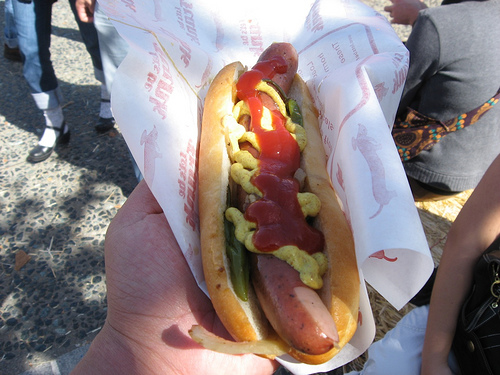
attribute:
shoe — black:
[17, 125, 68, 167]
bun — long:
[198, 62, 360, 367]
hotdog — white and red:
[194, 39, 365, 362]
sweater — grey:
[395, 7, 499, 182]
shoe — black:
[34, 106, 67, 174]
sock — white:
[27, 87, 75, 149]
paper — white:
[81, 10, 442, 362]